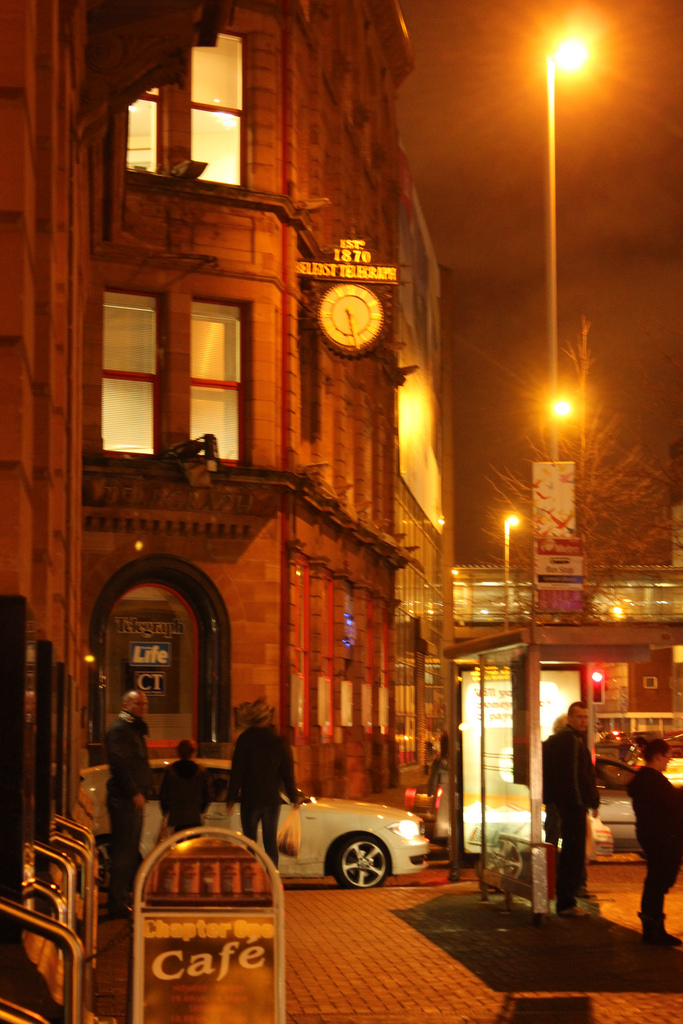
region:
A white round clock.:
[316, 279, 385, 352]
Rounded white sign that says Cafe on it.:
[131, 825, 287, 1023]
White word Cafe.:
[153, 943, 266, 982]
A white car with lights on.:
[83, 756, 427, 887]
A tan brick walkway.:
[94, 884, 681, 1022]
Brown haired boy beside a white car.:
[158, 740, 212, 844]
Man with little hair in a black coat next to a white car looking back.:
[104, 688, 153, 918]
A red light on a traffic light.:
[591, 670, 604, 683]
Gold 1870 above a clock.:
[330, 246, 370, 264]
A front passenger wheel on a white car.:
[332, 834, 390, 888]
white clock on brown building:
[3, 1, 421, 803]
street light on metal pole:
[538, 25, 609, 468]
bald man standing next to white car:
[79, 682, 432, 891]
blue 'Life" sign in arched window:
[91, 553, 229, 762]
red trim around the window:
[94, 282, 251, 483]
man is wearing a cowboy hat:
[223, 689, 309, 881]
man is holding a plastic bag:
[223, 684, 310, 888]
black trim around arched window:
[72, 547, 236, 762]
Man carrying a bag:
[271, 796, 305, 861]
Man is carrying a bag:
[272, 794, 312, 869]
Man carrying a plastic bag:
[272, 791, 312, 861]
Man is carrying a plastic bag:
[268, 797, 311, 863]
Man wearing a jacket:
[102, 704, 166, 806]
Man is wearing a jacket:
[98, 699, 163, 803]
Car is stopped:
[71, 751, 439, 900]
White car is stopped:
[68, 746, 463, 884]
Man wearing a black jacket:
[91, 697, 164, 803]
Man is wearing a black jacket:
[99, 695, 160, 802]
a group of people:
[88, 659, 341, 918]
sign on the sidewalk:
[111, 791, 311, 1020]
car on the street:
[70, 707, 467, 936]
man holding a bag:
[262, 774, 318, 866]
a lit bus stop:
[442, 612, 668, 925]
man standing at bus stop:
[535, 685, 625, 930]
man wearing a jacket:
[98, 702, 167, 813]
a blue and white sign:
[120, 628, 179, 673]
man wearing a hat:
[229, 691, 286, 736]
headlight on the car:
[386, 807, 426, 852]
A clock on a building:
[292, 230, 406, 362]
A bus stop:
[438, 604, 679, 924]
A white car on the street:
[78, 748, 430, 889]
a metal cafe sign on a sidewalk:
[123, 825, 288, 1022]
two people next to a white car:
[156, 694, 307, 894]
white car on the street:
[82, 748, 434, 892]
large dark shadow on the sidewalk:
[389, 884, 681, 996]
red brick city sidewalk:
[84, 877, 682, 1016]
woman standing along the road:
[620, 730, 681, 946]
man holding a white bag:
[542, 698, 616, 923]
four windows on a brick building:
[89, 1, 289, 492]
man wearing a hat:
[232, 694, 303, 854]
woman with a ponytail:
[618, 729, 681, 950]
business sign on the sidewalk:
[129, 822, 289, 1021]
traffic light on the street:
[578, 655, 612, 711]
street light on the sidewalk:
[536, 26, 593, 623]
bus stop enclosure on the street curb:
[447, 618, 554, 921]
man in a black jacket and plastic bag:
[225, 695, 300, 850]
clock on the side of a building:
[295, 233, 400, 539]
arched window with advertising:
[94, 543, 230, 685]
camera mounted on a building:
[163, 429, 230, 489]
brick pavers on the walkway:
[288, 891, 424, 1022]